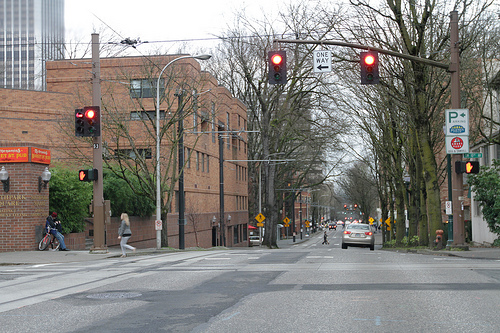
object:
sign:
[312, 51, 333, 71]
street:
[0, 220, 499, 331]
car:
[343, 221, 377, 251]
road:
[0, 218, 499, 331]